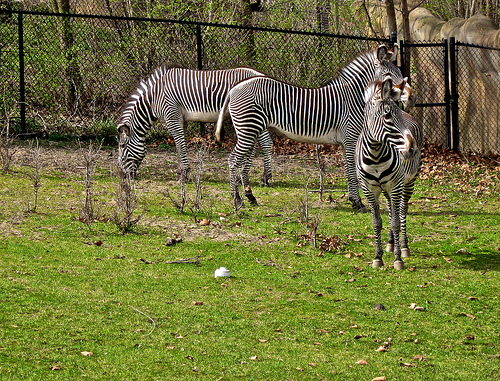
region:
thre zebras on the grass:
[81, 41, 467, 317]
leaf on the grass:
[407, 293, 427, 315]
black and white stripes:
[271, 87, 333, 134]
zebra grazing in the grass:
[106, 66, 283, 185]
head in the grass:
[99, 109, 166, 179]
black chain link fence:
[4, 9, 498, 141]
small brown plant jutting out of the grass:
[108, 173, 145, 236]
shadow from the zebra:
[418, 242, 499, 278]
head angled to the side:
[351, 73, 426, 170]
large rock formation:
[398, 13, 498, 137]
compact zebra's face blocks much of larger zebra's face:
[344, 36, 423, 163]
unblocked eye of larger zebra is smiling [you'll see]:
[379, 68, 394, 80]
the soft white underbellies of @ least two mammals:
[174, 106, 341, 161]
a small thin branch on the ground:
[120, 298, 160, 344]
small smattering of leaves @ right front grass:
[300, 282, 498, 379]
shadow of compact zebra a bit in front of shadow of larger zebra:
[329, 196, 499, 279]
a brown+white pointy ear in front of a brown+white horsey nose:
[389, 71, 419, 111]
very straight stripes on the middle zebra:
[260, 79, 345, 141]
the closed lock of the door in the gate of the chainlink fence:
[435, 89, 465, 114]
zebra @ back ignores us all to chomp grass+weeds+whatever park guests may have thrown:
[112, 57, 180, 183]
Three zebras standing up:
[94, 33, 434, 281]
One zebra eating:
[100, 52, 277, 199]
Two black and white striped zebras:
[210, 44, 430, 275]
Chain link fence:
[8, 8, 111, 136]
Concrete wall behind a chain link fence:
[393, 10, 495, 169]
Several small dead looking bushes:
[22, 163, 219, 243]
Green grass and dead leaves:
[243, 230, 388, 375]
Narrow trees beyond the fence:
[40, 0, 422, 70]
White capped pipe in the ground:
[209, 262, 239, 287]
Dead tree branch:
[116, 299, 163, 339]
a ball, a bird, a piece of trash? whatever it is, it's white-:
[208, 263, 234, 283]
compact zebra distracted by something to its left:
[350, 71, 429, 281]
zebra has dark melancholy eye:
[373, 106, 400, 128]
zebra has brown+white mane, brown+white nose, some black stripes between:
[360, 80, 420, 163]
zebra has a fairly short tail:
[205, 93, 235, 151]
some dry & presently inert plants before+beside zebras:
[0, 114, 365, 248]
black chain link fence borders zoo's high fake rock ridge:
[395, 0, 497, 166]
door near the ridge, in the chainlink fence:
[396, 35, 458, 152]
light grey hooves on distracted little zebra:
[368, 240, 415, 272]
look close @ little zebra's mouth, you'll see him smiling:
[394, 143, 419, 161]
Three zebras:
[167, 56, 417, 189]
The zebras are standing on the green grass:
[103, 243, 310, 378]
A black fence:
[54, 16, 153, 61]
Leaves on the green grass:
[353, 281, 441, 369]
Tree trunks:
[52, 22, 109, 101]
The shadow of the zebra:
[453, 245, 498, 278]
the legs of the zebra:
[349, 191, 422, 267]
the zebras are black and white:
[128, 70, 468, 230]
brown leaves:
[434, 149, 486, 194]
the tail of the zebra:
[199, 97, 234, 143]